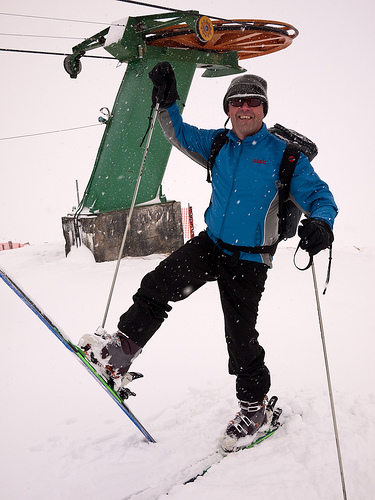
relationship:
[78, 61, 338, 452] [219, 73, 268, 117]
man wears hat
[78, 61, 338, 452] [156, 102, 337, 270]
man wears jacket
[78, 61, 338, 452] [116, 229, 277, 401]
man wears pants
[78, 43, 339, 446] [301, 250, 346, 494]
man holds ski pole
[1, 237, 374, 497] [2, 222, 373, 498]
snow on ground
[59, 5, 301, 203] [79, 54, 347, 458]
ski behind skier